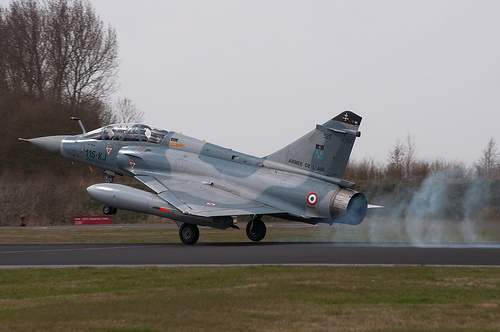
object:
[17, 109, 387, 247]
jet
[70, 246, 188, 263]
runway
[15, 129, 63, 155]
nose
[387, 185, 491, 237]
exhaust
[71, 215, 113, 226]
structure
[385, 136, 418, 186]
trees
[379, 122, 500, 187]
background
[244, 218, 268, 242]
wheels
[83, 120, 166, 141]
cockpit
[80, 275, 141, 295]
grass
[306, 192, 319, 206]
marks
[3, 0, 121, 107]
tree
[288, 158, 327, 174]
writing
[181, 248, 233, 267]
pavemet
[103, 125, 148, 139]
window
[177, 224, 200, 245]
wheel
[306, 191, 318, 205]
circle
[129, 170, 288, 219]
wing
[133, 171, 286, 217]
trangle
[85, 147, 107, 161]
letterig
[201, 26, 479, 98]
sky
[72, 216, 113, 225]
sign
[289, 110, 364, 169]
tail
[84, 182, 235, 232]
missile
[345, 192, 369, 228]
afterburner